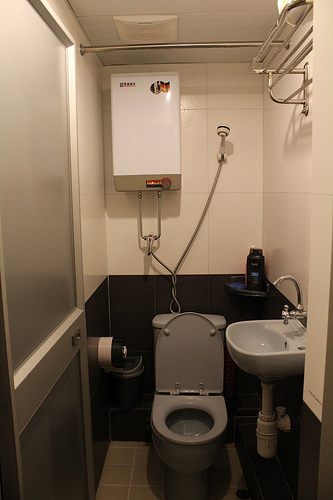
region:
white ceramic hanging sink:
[218, 295, 295, 381]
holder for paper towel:
[93, 326, 138, 374]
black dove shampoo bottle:
[221, 238, 272, 305]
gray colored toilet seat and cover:
[147, 314, 256, 461]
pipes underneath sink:
[239, 392, 291, 479]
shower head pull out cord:
[135, 140, 237, 329]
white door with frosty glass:
[32, 272, 93, 399]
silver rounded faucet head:
[263, 270, 324, 352]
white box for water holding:
[117, 72, 191, 205]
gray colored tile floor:
[102, 475, 154, 498]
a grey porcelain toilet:
[146, 310, 229, 497]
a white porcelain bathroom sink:
[219, 311, 307, 381]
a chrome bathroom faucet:
[268, 273, 306, 326]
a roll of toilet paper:
[89, 332, 128, 372]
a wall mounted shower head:
[213, 124, 232, 164]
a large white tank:
[104, 70, 184, 197]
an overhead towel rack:
[241, 1, 318, 108]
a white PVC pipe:
[249, 381, 290, 460]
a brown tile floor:
[97, 435, 250, 495]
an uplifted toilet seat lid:
[153, 310, 224, 393]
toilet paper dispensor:
[89, 333, 132, 384]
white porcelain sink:
[221, 265, 310, 460]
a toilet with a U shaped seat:
[143, 309, 232, 471]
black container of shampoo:
[238, 241, 267, 291]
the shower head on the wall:
[199, 113, 240, 179]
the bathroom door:
[3, 207, 106, 492]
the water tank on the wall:
[104, 68, 190, 189]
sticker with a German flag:
[147, 78, 173, 98]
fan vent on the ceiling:
[110, 14, 183, 48]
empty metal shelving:
[247, 34, 315, 116]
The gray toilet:
[147, 312, 229, 499]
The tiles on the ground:
[94, 437, 257, 498]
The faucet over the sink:
[273, 273, 307, 328]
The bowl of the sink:
[224, 314, 310, 382]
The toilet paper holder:
[94, 332, 129, 371]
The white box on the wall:
[104, 67, 184, 195]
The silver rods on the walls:
[75, 0, 314, 120]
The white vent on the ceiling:
[111, 12, 184, 46]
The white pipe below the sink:
[251, 378, 291, 463]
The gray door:
[0, 1, 97, 499]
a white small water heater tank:
[109, 71, 179, 189]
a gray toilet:
[151, 311, 235, 495]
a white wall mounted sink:
[226, 316, 310, 383]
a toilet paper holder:
[98, 337, 131, 376]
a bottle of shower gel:
[246, 248, 270, 291]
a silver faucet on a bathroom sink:
[273, 274, 308, 322]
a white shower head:
[213, 126, 234, 164]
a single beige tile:
[97, 463, 136, 487]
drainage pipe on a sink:
[253, 379, 293, 459]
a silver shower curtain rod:
[80, 40, 293, 57]